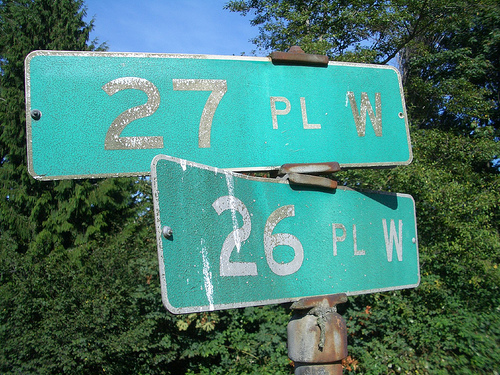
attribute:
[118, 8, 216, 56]
sky — blue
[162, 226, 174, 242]
screw — metal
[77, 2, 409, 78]
blue sky — clear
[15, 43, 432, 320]
markers — green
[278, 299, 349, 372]
post — grey, metal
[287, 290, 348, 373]
post — metal, rusting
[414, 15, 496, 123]
leaves — green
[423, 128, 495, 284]
leaves — green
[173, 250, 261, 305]
poop — dried, white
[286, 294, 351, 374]
rust — metal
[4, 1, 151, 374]
tree — growing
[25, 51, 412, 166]
post — green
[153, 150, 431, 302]
post — green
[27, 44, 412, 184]
street sign — green and white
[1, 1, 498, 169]
skies — clear, blue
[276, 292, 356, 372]
post — grey